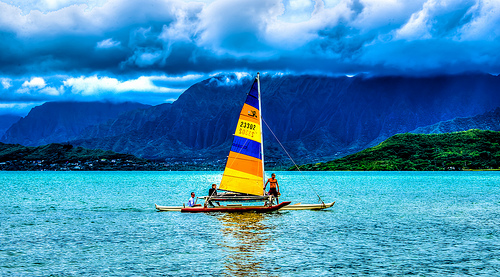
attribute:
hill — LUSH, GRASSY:
[332, 130, 493, 187]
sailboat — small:
[141, 103, 336, 215]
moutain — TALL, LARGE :
[80, 87, 217, 155]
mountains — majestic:
[2, 60, 499, 157]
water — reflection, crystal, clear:
[1, 167, 496, 271]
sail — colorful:
[185, 77, 310, 204]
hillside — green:
[306, 128, 499, 175]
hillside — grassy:
[1, 71, 496, 166]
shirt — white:
[205, 188, 219, 202]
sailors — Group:
[184, 176, 286, 206]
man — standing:
[263, 170, 282, 207]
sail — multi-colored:
[216, 72, 265, 196]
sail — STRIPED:
[181, 80, 280, 195]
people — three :
[180, 171, 283, 207]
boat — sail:
[154, 73, 335, 214]